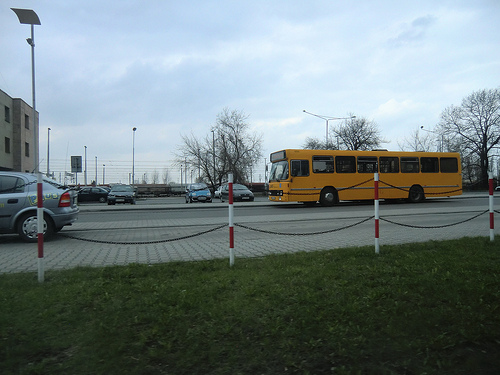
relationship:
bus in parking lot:
[260, 145, 471, 219] [99, 171, 480, 211]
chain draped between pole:
[233, 215, 373, 240] [371, 166, 383, 257]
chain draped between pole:
[233, 215, 373, 240] [223, 170, 238, 269]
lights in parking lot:
[123, 117, 142, 175] [1, 191, 499, 272]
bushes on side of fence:
[0, 233, 499, 373] [3, 172, 499, 280]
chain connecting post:
[31, 176, 496, 193] [224, 170, 236, 268]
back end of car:
[56, 185, 79, 225] [0, 170, 80, 239]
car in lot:
[186, 176, 214, 204] [1, 191, 497, 271]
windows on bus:
[309, 152, 464, 175] [265, 135, 466, 205]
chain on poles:
[22, 167, 482, 260] [364, 152, 431, 299]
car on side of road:
[0, 170, 80, 239] [0, 194, 488, 272]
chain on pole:
[43, 206, 497, 244] [360, 167, 397, 255]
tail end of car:
[48, 185, 77, 228] [0, 170, 80, 239]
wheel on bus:
[322, 186, 345, 211] [260, 137, 469, 209]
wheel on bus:
[403, 179, 430, 204] [260, 137, 469, 209]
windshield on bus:
[270, 159, 290, 181] [269, 147, 460, 207]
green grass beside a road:
[338, 286, 418, 336] [0, 194, 488, 272]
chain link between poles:
[231, 215, 373, 237] [225, 173, 380, 265]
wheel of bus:
[319, 186, 338, 205] [269, 147, 460, 207]